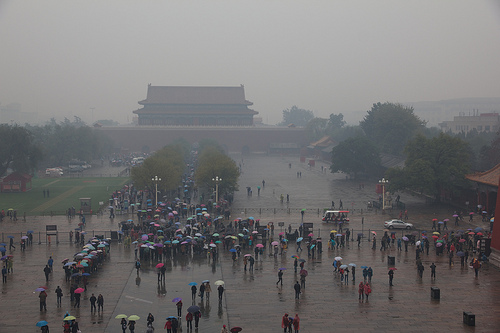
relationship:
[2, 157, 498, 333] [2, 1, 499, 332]
peope in rain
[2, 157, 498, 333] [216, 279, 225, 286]
peope have umbrellas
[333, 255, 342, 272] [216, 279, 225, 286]
person has an umbrellas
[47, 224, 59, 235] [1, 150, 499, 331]
object on ground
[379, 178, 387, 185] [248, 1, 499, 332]
light on right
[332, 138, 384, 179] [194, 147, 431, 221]
tree in plaza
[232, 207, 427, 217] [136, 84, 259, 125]
fence in front of building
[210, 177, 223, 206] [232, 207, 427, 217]
street light next to fence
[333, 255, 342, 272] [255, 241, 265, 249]
person has an umbrella